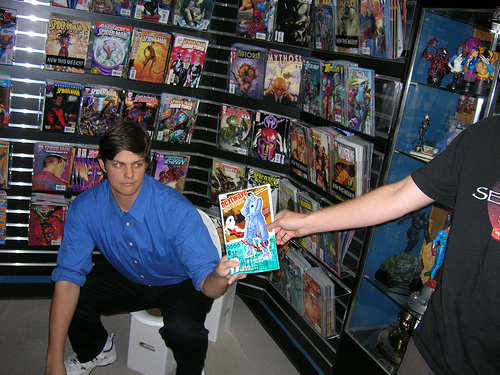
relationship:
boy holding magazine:
[26, 123, 240, 374] [216, 183, 282, 276]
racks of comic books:
[2, 1, 406, 371] [1, 1, 399, 344]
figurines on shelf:
[427, 35, 496, 100] [418, 19, 499, 101]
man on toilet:
[26, 123, 240, 374] [125, 211, 234, 365]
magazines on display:
[35, 0, 399, 343] [32, 3, 396, 352]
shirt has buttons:
[53, 180, 227, 300] [122, 222, 152, 285]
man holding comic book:
[26, 123, 240, 374] [216, 183, 282, 276]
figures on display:
[427, 35, 496, 100] [409, 11, 498, 104]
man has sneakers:
[26, 123, 240, 374] [61, 336, 119, 374]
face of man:
[95, 124, 154, 193] [26, 123, 240, 374]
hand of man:
[265, 207, 309, 248] [266, 90, 500, 368]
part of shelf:
[407, 73, 497, 104] [418, 19, 499, 101]